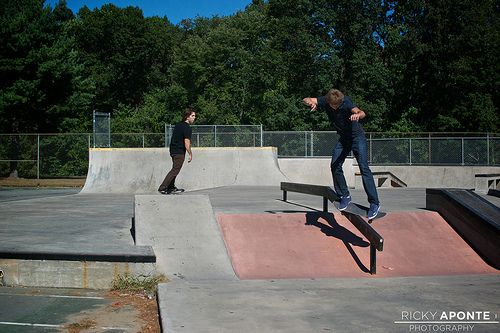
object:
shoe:
[367, 201, 381, 219]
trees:
[134, 40, 146, 57]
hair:
[182, 108, 196, 122]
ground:
[0, 183, 500, 332]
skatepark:
[0, 0, 500, 333]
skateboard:
[333, 198, 388, 225]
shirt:
[169, 121, 193, 155]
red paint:
[216, 209, 500, 281]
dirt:
[61, 289, 163, 332]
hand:
[348, 114, 360, 123]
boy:
[157, 109, 199, 196]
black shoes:
[157, 186, 178, 194]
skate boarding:
[277, 81, 390, 275]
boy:
[300, 88, 382, 221]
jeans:
[330, 137, 380, 204]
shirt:
[316, 95, 365, 139]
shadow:
[265, 194, 371, 272]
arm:
[351, 104, 367, 120]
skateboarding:
[154, 86, 386, 222]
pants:
[158, 153, 185, 191]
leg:
[352, 134, 381, 220]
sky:
[42, 0, 407, 59]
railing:
[279, 181, 385, 276]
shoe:
[337, 195, 351, 212]